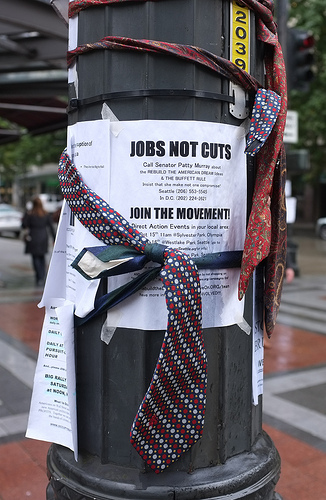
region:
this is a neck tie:
[135, 243, 224, 436]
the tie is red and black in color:
[164, 358, 202, 413]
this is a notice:
[134, 139, 231, 208]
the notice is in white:
[147, 159, 239, 213]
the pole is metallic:
[91, 359, 138, 398]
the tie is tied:
[135, 235, 194, 279]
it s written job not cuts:
[126, 139, 236, 161]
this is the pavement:
[282, 402, 313, 426]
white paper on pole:
[96, 125, 241, 315]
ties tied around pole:
[0, 164, 241, 471]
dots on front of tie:
[145, 376, 192, 444]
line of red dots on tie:
[154, 425, 169, 444]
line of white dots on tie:
[163, 414, 176, 442]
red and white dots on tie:
[153, 392, 193, 428]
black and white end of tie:
[67, 243, 137, 283]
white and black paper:
[28, 301, 76, 458]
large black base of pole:
[46, 326, 281, 498]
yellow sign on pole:
[218, 2, 257, 65]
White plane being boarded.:
[225, 246, 243, 294]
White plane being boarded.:
[259, 282, 286, 403]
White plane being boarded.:
[286, 172, 295, 229]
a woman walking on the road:
[16, 189, 56, 290]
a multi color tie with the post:
[150, 256, 206, 458]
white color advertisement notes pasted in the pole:
[103, 118, 238, 335]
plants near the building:
[11, 131, 60, 187]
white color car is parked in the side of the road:
[1, 197, 20, 234]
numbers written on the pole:
[228, 6, 252, 112]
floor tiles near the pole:
[293, 450, 319, 498]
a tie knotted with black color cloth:
[81, 206, 206, 305]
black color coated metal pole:
[84, 13, 268, 482]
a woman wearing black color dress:
[22, 212, 53, 282]